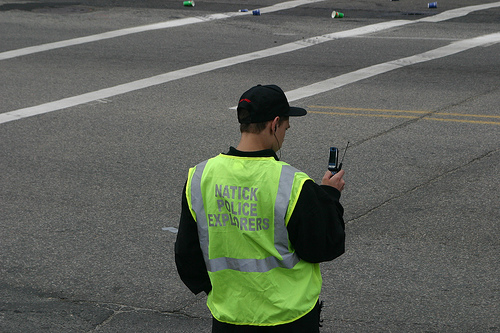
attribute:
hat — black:
[220, 81, 299, 118]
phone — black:
[314, 139, 347, 171]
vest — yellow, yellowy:
[177, 160, 305, 315]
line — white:
[33, 80, 165, 123]